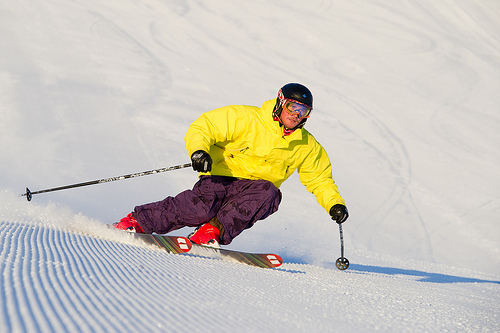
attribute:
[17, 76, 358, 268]
man — skiing, inclined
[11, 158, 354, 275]
pair — skis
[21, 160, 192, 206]
ski pole — here, outstretched, black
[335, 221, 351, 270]
ski pole — here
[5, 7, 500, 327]
ground — covered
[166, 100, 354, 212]
jacket — yellow, fastened, bright, ski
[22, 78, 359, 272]
skier — leaning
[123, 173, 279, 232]
pants — purple, loose, baggy, ski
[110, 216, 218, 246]
shoes — red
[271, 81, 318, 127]
helmet — black, shiny, safety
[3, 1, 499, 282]
hillside — covered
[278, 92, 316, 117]
goggles — red, safety, ski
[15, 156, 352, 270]
skis — red, green, pair, silver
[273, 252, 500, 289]
shadow — skier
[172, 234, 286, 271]
tips — red, white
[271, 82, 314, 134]
head — man's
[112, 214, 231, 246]
boots — red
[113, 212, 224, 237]
feet — skier's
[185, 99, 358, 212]
coat — yellow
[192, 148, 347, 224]
gloves — black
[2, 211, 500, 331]
marks — skis